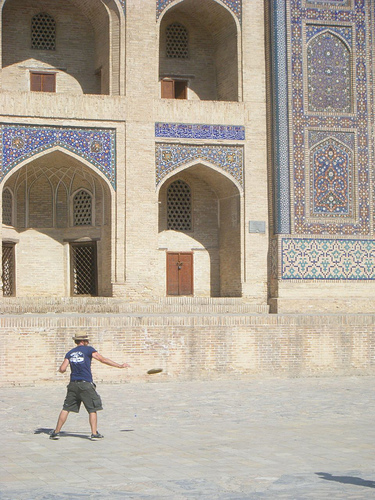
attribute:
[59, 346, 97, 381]
t-shirt — blue 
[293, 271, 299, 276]
design — blue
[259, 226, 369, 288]
design — blue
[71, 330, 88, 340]
hat — brown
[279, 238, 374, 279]
design — blue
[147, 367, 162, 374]
frisbee — airborne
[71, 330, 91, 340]
hat — light brown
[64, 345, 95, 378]
shirt — blue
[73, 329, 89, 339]
hat — yellow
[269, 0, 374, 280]
design — blue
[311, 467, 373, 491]
shadow — person's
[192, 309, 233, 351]
wall — brick 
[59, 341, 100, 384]
t-shirt — blue 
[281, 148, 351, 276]
colorful tiled — colorful 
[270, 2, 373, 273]
wall — tiled 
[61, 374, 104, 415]
green pants — dark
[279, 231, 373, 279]
design — blue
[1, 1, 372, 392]
building — blue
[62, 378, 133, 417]
shorts — cargo style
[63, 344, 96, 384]
shirt — blue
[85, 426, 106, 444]
shoe — black 